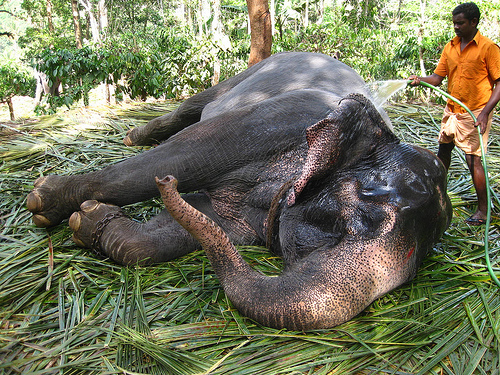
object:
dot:
[399, 252, 404, 255]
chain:
[90, 210, 129, 250]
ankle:
[112, 221, 157, 267]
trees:
[0, 0, 499, 114]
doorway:
[0, 78, 499, 374]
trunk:
[153, 176, 367, 332]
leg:
[25, 95, 226, 269]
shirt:
[433, 29, 500, 113]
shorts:
[438, 104, 494, 157]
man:
[406, 3, 499, 226]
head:
[451, 2, 480, 38]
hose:
[407, 79, 500, 286]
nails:
[25, 191, 43, 210]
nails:
[68, 212, 81, 233]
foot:
[26, 176, 76, 228]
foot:
[68, 199, 124, 248]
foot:
[122, 126, 147, 147]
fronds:
[0, 329, 499, 369]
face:
[282, 149, 453, 268]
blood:
[407, 243, 417, 259]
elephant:
[28, 51, 452, 330]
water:
[355, 80, 407, 114]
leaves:
[0, 0, 438, 85]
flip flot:
[468, 216, 487, 221]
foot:
[465, 200, 487, 226]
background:
[0, 0, 499, 115]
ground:
[0, 97, 500, 375]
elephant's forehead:
[154, 94, 453, 331]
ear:
[287, 91, 396, 207]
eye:
[360, 209, 377, 227]